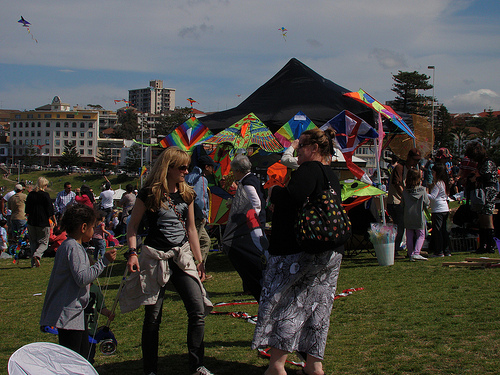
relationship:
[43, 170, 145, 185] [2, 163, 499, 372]
shadows are on grass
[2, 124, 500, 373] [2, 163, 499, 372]
people are in a field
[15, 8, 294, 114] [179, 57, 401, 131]
kites are on a tent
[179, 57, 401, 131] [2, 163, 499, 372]
tent in a field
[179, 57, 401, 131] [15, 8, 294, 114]
tent has kites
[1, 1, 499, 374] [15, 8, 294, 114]
area has kites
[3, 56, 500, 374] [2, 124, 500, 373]
festival has people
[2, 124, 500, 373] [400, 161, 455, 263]
people have children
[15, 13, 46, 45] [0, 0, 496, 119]
kite in sky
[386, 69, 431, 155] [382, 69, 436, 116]
tree has green leaves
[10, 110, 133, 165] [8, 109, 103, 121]
building has a yellow top floor